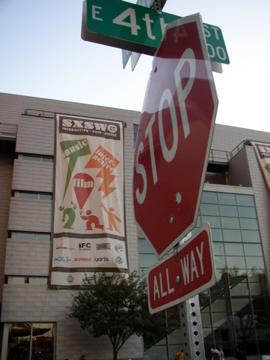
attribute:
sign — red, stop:
[127, 11, 221, 261]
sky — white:
[79, 66, 87, 70]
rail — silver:
[25, 82, 78, 157]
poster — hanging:
[256, 129, 264, 164]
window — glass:
[200, 288, 248, 335]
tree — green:
[104, 262, 142, 327]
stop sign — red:
[95, 29, 241, 257]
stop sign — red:
[141, 78, 259, 247]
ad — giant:
[46, 108, 138, 288]